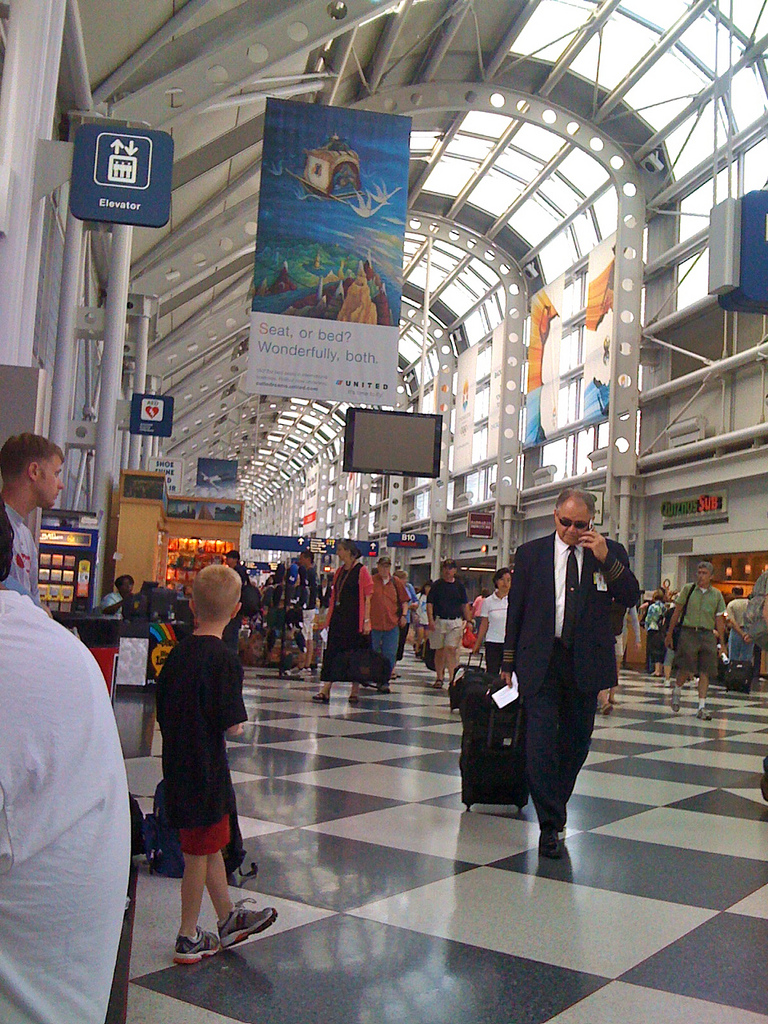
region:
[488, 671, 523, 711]
a white envelope in a man's hand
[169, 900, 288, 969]
black and grey sneakers with orange on their soles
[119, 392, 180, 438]
a red heart on a sign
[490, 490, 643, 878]
an airplane pilot walking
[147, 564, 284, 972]
a young boy with short blonde hair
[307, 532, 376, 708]
a woman wearing a coral colored sweater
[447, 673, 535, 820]
a black suitcase on wheels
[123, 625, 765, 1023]
a floor of large black and white tiles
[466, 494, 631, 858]
a man pulling a suitcase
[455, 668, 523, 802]
a black suitcase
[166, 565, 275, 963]
a boy wearing red shorts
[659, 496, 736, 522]
a sign on the wall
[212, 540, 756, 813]
people walking down a hall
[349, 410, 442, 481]
a television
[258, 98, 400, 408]
a sign hanging from the ceiling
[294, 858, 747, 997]
blue and white tile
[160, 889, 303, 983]
the shoes are grey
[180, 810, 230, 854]
the shorts are red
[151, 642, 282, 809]
the shirt is black in color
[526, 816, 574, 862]
the shirt is black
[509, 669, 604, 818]
the pants are navy blue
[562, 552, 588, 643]
the tie is black in color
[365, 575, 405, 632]
the shirt is orange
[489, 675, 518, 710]
a white piece of paper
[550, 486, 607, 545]
the head of a man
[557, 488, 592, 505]
the hair of a man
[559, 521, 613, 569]
the hand of a man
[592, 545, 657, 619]
the arm of a man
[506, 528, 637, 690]
the suit jacket of a man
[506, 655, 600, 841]
the pants of a man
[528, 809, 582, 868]
the shoes of a man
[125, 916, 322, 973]
the shoes of a child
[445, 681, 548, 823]
a big black suitcase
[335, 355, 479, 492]
A person eating a orange.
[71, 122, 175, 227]
Blue sign that says ELEVATOR.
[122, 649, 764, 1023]
A long black and white checkered floor.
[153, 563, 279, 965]
Boy in red shorts with shaved head.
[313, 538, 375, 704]
Grey haired woman in black dress with pink coat.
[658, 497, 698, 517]
Green sign that says Quiznos.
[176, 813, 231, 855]
Red shorts on a boy with a shaved head.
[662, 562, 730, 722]
Grey haired man in green shirt and white socks.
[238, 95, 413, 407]
Large rectangle banner that says Seat, or bed?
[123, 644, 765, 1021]
A black and white checkered floor with reflections on it.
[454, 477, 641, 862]
man pulling black luggage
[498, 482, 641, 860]
man wearing navy blue suit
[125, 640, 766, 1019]
black and white checkered floor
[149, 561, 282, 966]
boy wearing black shirt and red shorts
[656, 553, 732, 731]
man holding white object wearing green shirt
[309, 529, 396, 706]
woman carrying a dufflebag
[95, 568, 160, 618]
woman sitting in front of cash register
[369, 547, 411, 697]
man wearing orange shirt and blue jeans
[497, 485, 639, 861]
man talking on a cellphone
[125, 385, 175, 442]
blue sign with a red heart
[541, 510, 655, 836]
a person walking inside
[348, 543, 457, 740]
a person walking inside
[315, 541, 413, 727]
a person walking inside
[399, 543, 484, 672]
a person walking inside